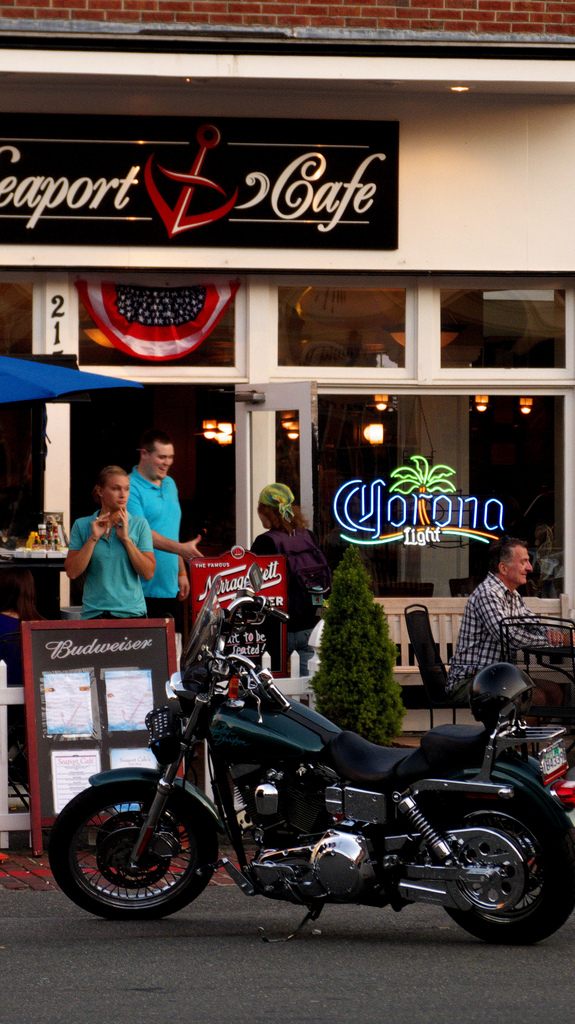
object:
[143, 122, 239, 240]
anchor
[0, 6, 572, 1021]
picture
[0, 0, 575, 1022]
outdoors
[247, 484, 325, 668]
woman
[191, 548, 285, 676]
boards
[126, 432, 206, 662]
man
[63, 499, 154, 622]
blue shirts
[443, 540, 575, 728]
man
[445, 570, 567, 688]
shirt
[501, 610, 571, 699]
table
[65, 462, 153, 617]
woman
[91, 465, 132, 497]
hair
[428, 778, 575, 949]
wheel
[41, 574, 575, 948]
motorcycle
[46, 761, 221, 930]
wheel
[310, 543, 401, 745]
evergreen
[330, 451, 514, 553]
neon sign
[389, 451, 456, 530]
tree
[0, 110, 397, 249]
sign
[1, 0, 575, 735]
building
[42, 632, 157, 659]
budweiser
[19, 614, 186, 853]
board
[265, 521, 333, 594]
purple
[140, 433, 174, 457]
hair